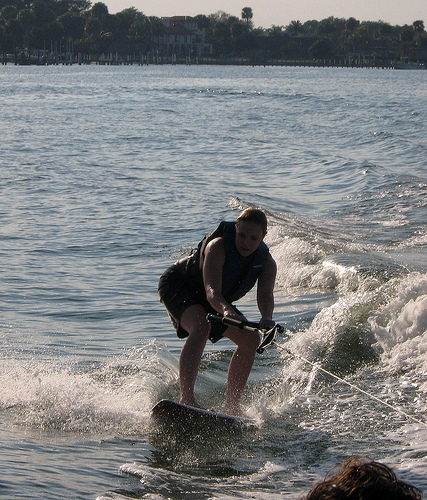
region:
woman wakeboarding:
[132, 197, 426, 487]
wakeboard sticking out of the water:
[135, 394, 274, 434]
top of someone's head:
[297, 447, 425, 498]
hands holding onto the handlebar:
[202, 295, 303, 352]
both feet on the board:
[172, 383, 260, 414]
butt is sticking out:
[132, 247, 204, 328]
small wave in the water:
[250, 217, 425, 403]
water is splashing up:
[151, 404, 237, 474]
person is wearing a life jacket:
[183, 216, 280, 318]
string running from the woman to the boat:
[270, 339, 425, 457]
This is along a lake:
[49, 101, 404, 447]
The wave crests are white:
[260, 237, 366, 378]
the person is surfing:
[158, 213, 325, 404]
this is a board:
[123, 376, 250, 482]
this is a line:
[255, 317, 425, 468]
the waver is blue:
[42, 61, 294, 183]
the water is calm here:
[47, 103, 268, 250]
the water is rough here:
[309, 219, 409, 370]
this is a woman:
[128, 198, 305, 391]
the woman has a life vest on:
[142, 193, 356, 383]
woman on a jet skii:
[147, 210, 422, 447]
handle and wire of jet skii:
[202, 307, 425, 434]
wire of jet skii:
[272, 341, 425, 434]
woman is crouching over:
[155, 199, 283, 412]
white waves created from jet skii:
[7, 176, 419, 459]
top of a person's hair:
[306, 454, 411, 498]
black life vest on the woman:
[196, 223, 267, 299]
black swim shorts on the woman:
[155, 265, 237, 342]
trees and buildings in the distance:
[3, 0, 424, 71]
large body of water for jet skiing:
[4, 64, 422, 495]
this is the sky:
[266, 2, 296, 17]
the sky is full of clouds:
[263, 2, 287, 17]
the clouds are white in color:
[266, 3, 285, 21]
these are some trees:
[51, 8, 118, 42]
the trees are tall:
[318, 16, 391, 51]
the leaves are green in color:
[95, 5, 112, 24]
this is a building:
[159, 16, 213, 53]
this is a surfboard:
[148, 399, 222, 422]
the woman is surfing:
[151, 198, 281, 410]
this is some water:
[42, 85, 396, 189]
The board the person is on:
[150, 395, 256, 427]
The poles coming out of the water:
[15, 35, 407, 72]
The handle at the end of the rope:
[203, 305, 288, 353]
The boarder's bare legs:
[173, 312, 262, 416]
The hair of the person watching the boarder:
[298, 448, 422, 499]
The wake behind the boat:
[3, 144, 426, 481]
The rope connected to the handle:
[267, 334, 426, 424]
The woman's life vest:
[178, 216, 273, 317]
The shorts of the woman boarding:
[146, 258, 246, 344]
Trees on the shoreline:
[1, 0, 426, 62]